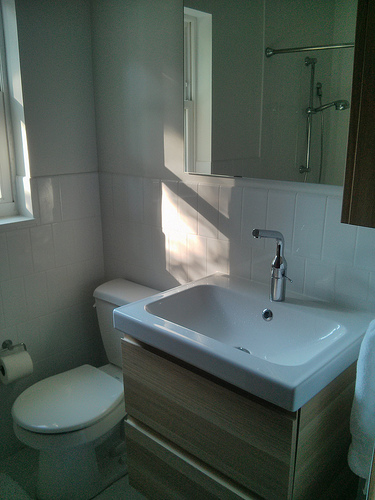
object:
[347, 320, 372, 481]
towel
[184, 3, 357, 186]
reflection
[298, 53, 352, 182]
shower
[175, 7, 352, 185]
mirror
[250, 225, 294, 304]
bathroom faucet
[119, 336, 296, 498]
drawer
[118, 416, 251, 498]
drawer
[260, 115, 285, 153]
ground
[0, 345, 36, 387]
toilet paper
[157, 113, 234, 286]
light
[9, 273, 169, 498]
toilet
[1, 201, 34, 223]
sill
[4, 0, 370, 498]
bathroom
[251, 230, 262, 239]
faucet nozzle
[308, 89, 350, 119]
reflection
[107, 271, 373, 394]
sink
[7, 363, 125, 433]
toilet seat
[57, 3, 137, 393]
corner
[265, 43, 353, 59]
curtain rod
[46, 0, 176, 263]
wall